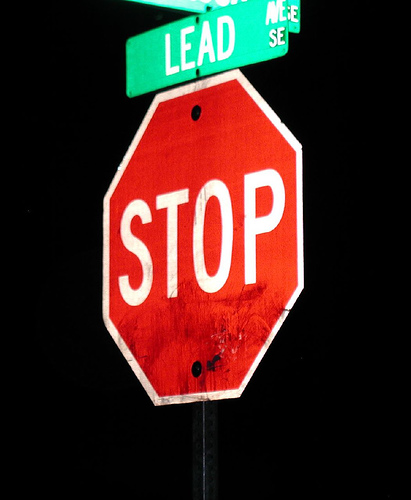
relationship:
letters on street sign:
[162, 15, 234, 76] [125, 2, 290, 101]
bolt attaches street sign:
[191, 14, 204, 26] [125, 2, 290, 101]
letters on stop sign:
[118, 168, 284, 309] [101, 68, 303, 407]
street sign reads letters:
[125, 2, 290, 101] [213, 15, 232, 62]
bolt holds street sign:
[191, 14, 204, 26] [125, 2, 290, 101]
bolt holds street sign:
[193, 14, 199, 26] [125, 2, 290, 101]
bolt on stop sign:
[191, 105, 201, 120] [101, 68, 303, 407]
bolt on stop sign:
[191, 359, 203, 378] [101, 68, 303, 407]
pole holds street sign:
[188, 403, 216, 497] [125, 2, 290, 101]